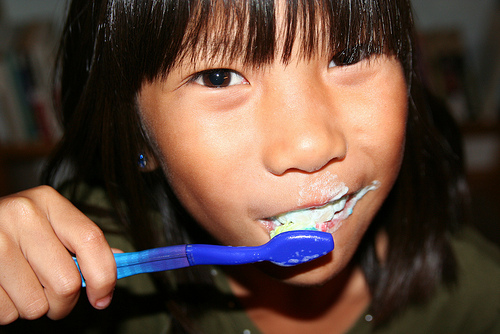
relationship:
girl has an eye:
[2, 1, 500, 330] [191, 67, 251, 91]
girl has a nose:
[2, 1, 500, 330] [262, 121, 348, 173]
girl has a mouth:
[2, 1, 500, 330] [260, 186, 363, 238]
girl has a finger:
[2, 1, 500, 330] [49, 195, 117, 310]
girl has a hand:
[2, 1, 500, 330] [1, 185, 119, 326]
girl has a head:
[2, 1, 500, 330] [111, 3, 414, 291]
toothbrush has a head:
[70, 216, 338, 286] [270, 223, 337, 270]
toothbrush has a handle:
[70, 216, 338, 286] [64, 235, 268, 304]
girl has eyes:
[2, 1, 500, 330] [186, 41, 378, 91]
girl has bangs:
[2, 1, 500, 330] [106, 0, 404, 85]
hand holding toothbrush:
[1, 185, 119, 326] [70, 216, 338, 286]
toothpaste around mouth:
[291, 176, 380, 234] [260, 186, 363, 238]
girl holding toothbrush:
[2, 1, 500, 330] [70, 216, 338, 286]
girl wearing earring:
[2, 1, 500, 330] [137, 149, 147, 169]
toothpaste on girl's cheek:
[291, 176, 380, 234] [299, 176, 383, 217]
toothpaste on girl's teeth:
[291, 176, 380, 234] [279, 199, 350, 232]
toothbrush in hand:
[70, 216, 338, 286] [1, 185, 119, 326]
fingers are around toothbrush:
[1, 185, 119, 326] [70, 216, 338, 286]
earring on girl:
[137, 149, 147, 169] [2, 1, 500, 330]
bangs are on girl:
[106, 0, 404, 85] [2, 1, 500, 330]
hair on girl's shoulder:
[36, 1, 473, 332] [12, 180, 499, 331]